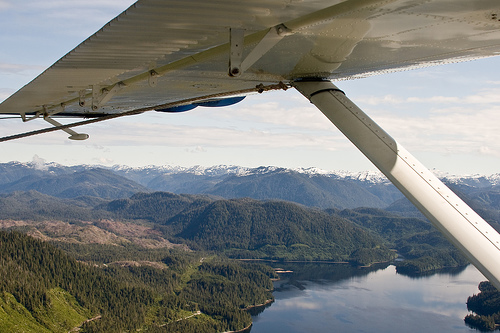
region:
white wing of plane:
[2, 0, 498, 162]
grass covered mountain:
[148, 185, 390, 264]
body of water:
[248, 254, 493, 330]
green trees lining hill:
[8, 228, 154, 331]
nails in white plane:
[388, 141, 433, 185]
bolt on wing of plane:
[224, 64, 244, 79]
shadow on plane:
[296, 84, 432, 206]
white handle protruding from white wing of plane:
[31, 113, 100, 159]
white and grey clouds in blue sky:
[171, 125, 268, 158]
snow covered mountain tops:
[165, 158, 331, 198]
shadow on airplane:
[291, 80, 426, 186]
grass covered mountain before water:
[111, 185, 394, 265]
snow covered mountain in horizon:
[136, 155, 312, 197]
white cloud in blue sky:
[408, 87, 485, 126]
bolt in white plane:
[221, 64, 246, 80]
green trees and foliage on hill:
[4, 227, 79, 314]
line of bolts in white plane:
[410, 163, 499, 251]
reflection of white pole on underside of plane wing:
[287, 8, 383, 88]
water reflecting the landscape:
[320, 280, 416, 330]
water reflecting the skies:
[297, 291, 417, 328]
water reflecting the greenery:
[285, 276, 393, 329]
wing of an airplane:
[15, 0, 495, 126]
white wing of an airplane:
[10, 1, 495, 119]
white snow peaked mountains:
[5, 150, 345, 192]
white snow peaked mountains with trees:
[12, 153, 341, 245]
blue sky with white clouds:
[392, 70, 497, 136]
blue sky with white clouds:
[141, 122, 315, 160]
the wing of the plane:
[27, 17, 370, 193]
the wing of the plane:
[2, 28, 262, 105]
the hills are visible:
[68, 143, 370, 313]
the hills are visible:
[107, 158, 294, 256]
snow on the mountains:
[26, 158, 392, 180]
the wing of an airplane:
[8, 20, 479, 219]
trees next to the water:
[213, 259, 258, 331]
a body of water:
[243, 253, 496, 329]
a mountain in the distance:
[20, 153, 395, 204]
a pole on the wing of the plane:
[308, 72, 498, 312]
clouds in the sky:
[132, 125, 292, 159]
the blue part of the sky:
[14, 24, 53, 49]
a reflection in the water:
[267, 255, 315, 295]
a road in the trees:
[148, 305, 205, 324]